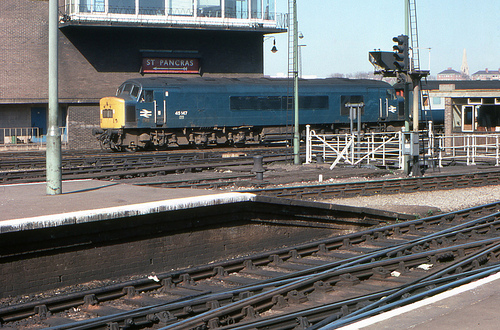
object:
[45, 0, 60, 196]
pole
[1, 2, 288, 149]
building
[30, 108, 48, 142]
door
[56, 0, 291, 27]
wire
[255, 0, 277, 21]
windows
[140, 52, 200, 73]
sign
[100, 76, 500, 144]
train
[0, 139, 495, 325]
rail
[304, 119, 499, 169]
fence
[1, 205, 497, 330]
track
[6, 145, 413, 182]
track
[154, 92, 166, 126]
door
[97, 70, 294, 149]
engine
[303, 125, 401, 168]
rails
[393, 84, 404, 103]
street sign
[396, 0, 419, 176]
pole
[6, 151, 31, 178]
rail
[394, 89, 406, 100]
traffic signal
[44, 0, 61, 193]
post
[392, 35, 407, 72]
light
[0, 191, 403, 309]
hole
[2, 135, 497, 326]
ground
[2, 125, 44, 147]
railing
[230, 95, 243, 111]
window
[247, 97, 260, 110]
window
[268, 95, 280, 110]
window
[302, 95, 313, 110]
window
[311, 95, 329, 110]
window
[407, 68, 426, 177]
post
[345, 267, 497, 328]
platform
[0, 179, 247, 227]
platform